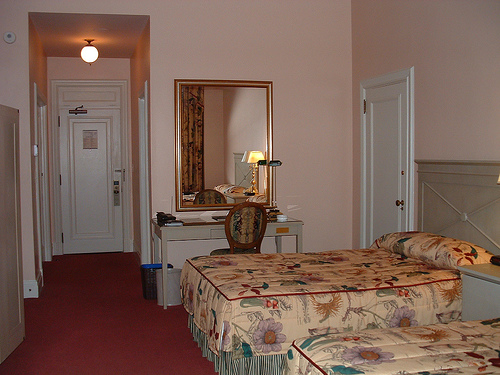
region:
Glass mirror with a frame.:
[163, 75, 278, 215]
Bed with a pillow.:
[174, 156, 499, 364]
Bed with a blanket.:
[175, 155, 498, 364]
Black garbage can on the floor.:
[131, 260, 173, 305]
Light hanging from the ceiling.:
[41, 6, 136, 81]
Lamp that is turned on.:
[241, 143, 273, 206]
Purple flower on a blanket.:
[181, 256, 469, 373]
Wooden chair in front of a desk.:
[201, 198, 275, 267]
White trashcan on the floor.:
[153, 263, 185, 307]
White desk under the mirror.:
[147, 206, 309, 311]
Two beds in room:
[171, 153, 491, 373]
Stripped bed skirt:
[172, 292, 334, 373]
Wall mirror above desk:
[167, 69, 282, 218]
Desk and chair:
[130, 193, 331, 285]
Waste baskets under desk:
[130, 250, 183, 301]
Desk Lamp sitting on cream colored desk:
[260, 150, 296, 241]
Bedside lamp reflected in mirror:
[225, 140, 281, 205]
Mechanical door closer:
[57, 100, 102, 125]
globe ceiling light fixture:
[61, 30, 117, 80]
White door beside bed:
[349, 66, 411, 274]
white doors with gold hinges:
[353, 69, 420, 243]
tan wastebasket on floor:
[153, 264, 188, 312]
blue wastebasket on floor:
[134, 256, 169, 301]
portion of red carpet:
[67, 264, 152, 359]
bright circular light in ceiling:
[72, 26, 106, 81]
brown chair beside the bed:
[211, 199, 270, 269]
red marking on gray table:
[271, 224, 298, 241]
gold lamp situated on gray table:
[241, 144, 278, 209]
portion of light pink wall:
[282, 29, 347, 161]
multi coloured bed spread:
[183, 251, 498, 327]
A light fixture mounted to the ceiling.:
[67, 34, 115, 71]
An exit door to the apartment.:
[55, 74, 136, 256]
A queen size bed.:
[171, 226, 493, 355]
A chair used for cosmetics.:
[201, 196, 268, 261]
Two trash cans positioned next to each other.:
[130, 249, 195, 312]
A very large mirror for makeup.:
[169, 78, 276, 213]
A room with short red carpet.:
[32, 250, 149, 365]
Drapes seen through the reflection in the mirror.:
[172, 78, 210, 195]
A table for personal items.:
[146, 205, 306, 310]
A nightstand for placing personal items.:
[452, 251, 499, 323]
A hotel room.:
[16, 5, 481, 369]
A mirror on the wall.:
[168, 69, 292, 211]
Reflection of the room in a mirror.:
[173, 72, 280, 214]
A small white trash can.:
[139, 252, 189, 310]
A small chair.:
[216, 195, 276, 252]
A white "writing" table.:
[146, 192, 312, 274]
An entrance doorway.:
[47, 65, 140, 270]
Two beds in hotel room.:
[180, 215, 487, 370]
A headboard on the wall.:
[413, 140, 498, 245]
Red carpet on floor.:
[46, 269, 141, 364]